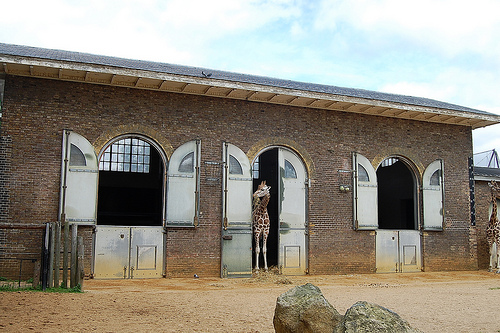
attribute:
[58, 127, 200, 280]
stable — open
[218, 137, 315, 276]
stable — open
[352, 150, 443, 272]
stable — open, Three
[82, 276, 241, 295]
floor — dirt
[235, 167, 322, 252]
giraffe — looking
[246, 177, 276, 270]
giraffe — on the side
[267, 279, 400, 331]
rock — big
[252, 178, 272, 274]
giraffe — small, brown, white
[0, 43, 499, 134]
roof — black, tile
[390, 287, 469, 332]
dirt — floor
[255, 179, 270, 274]
giraffe — looking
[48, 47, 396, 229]
building — big, brick 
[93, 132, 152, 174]
window — small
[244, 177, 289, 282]
giraffe — Small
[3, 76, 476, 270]
brick — Brown, of stable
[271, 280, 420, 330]
rocks — large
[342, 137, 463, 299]
door — White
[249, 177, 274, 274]
giraffe — brown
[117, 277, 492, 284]
floor — dirt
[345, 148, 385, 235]
half door — open, half 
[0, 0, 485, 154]
sky — blue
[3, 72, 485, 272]
wall — brown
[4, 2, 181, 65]
clouds — white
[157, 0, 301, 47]
clouds — white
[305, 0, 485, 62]
clouds — white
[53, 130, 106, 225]
doors — grey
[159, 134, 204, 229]
doors — grey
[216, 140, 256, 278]
doors — grey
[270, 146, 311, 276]
doors — grey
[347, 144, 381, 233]
doors — grey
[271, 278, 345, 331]
rock — brown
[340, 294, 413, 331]
rock — brown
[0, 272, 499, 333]
area — dirt